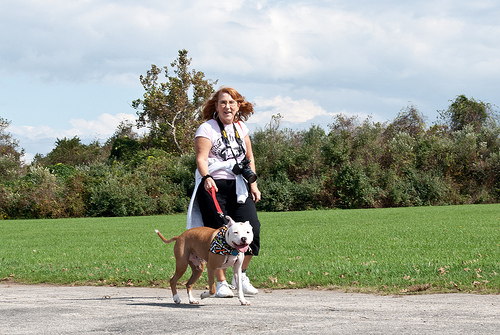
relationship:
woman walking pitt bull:
[193, 87, 260, 297] [153, 220, 253, 305]